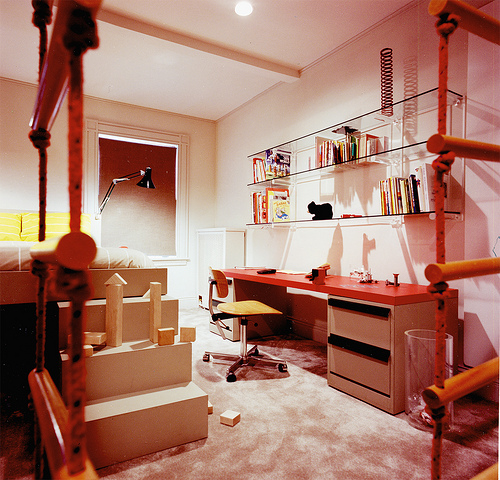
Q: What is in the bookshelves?
A: Books.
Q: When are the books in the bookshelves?
A: Now.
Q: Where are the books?
A: In the bookshelves.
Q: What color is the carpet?
A: Off white.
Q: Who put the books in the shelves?
A: A person.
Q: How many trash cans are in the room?
A: One.